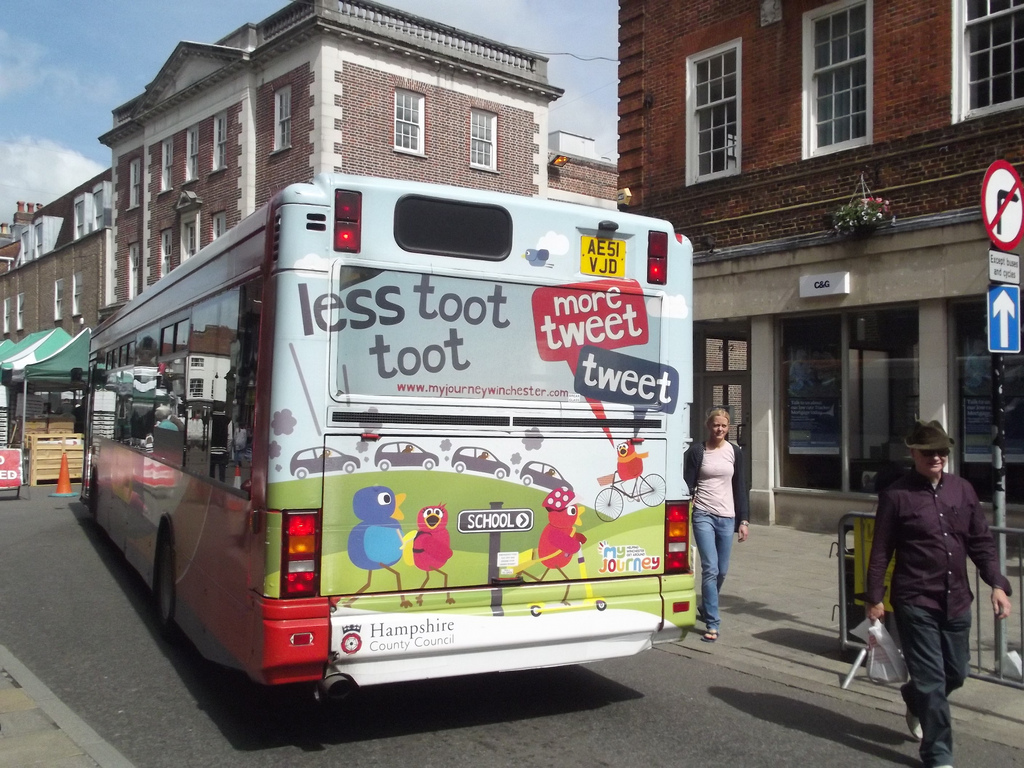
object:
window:
[392, 86, 428, 159]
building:
[96, 0, 565, 325]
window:
[469, 106, 501, 175]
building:
[307, 0, 564, 198]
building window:
[208, 109, 228, 175]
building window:
[158, 136, 175, 196]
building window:
[72, 271, 81, 317]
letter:
[298, 284, 314, 337]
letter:
[314, 293, 349, 332]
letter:
[413, 274, 438, 320]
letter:
[375, 285, 405, 325]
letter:
[397, 346, 421, 376]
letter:
[347, 289, 377, 330]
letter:
[463, 297, 487, 327]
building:
[685, 37, 742, 188]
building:
[802, 0, 874, 161]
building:
[269, 84, 293, 156]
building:
[206, 108, 228, 177]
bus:
[79, 173, 697, 705]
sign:
[532, 279, 649, 362]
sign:
[988, 284, 1023, 354]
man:
[851, 419, 1012, 768]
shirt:
[852, 464, 1013, 621]